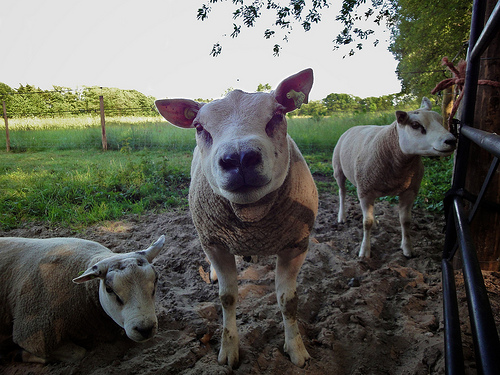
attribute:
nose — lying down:
[133, 319, 155, 339]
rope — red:
[442, 57, 487, 122]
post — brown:
[98, 93, 108, 148]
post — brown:
[4, 109, 17, 151]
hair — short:
[112, 254, 122, 261]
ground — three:
[383, 168, 403, 200]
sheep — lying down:
[0, 228, 172, 372]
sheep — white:
[149, 59, 336, 373]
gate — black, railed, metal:
[443, 2, 498, 373]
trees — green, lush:
[0, 2, 470, 110]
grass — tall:
[5, 88, 440, 220]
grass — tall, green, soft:
[53, 115, 427, 130]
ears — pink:
[155, 69, 321, 128]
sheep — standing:
[149, 66, 321, 362]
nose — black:
[219, 145, 266, 191]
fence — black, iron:
[439, 0, 497, 375]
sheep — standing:
[329, 95, 458, 261]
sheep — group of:
[27, 70, 474, 372]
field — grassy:
[48, 92, 414, 199]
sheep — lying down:
[6, 223, 156, 333]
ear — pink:
[276, 68, 316, 111]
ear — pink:
[152, 96, 197, 128]